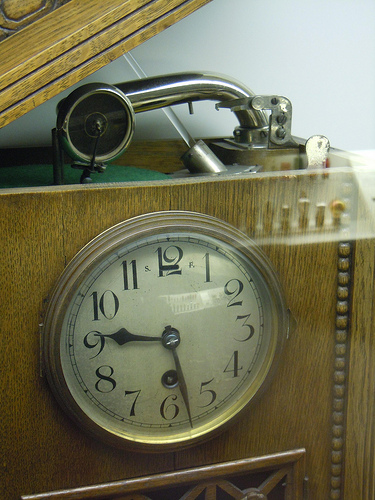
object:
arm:
[94, 328, 164, 345]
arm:
[170, 343, 196, 431]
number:
[89, 290, 121, 322]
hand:
[169, 345, 199, 431]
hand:
[100, 326, 165, 348]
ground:
[304, 135, 329, 170]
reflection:
[158, 286, 230, 318]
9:
[82, 330, 105, 360]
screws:
[276, 113, 287, 140]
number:
[123, 388, 141, 417]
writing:
[87, 289, 119, 321]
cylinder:
[182, 139, 228, 176]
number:
[95, 363, 117, 392]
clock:
[42, 210, 287, 460]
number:
[196, 377, 218, 409]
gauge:
[53, 81, 137, 184]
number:
[233, 313, 255, 342]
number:
[154, 243, 184, 279]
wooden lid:
[0, 1, 219, 127]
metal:
[33, 70, 332, 183]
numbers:
[223, 350, 244, 378]